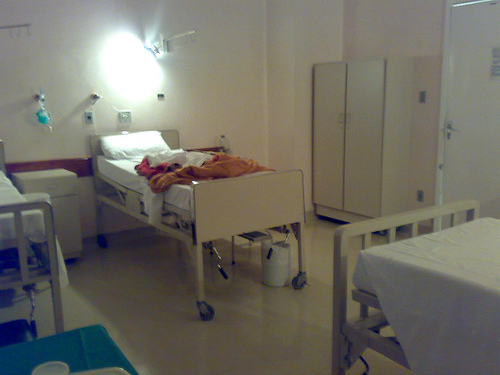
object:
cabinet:
[311, 59, 395, 232]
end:
[189, 174, 311, 209]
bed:
[76, 110, 317, 231]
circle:
[93, 34, 178, 110]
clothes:
[128, 145, 194, 167]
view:
[91, 122, 265, 196]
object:
[259, 234, 293, 292]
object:
[80, 111, 95, 125]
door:
[435, 2, 497, 198]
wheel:
[96, 229, 111, 252]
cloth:
[17, 319, 132, 372]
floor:
[139, 321, 211, 365]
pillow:
[98, 124, 179, 157]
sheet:
[160, 148, 198, 161]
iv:
[29, 96, 61, 129]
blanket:
[153, 154, 280, 187]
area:
[329, 10, 403, 51]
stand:
[82, 91, 114, 110]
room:
[4, 9, 499, 354]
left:
[28, 133, 85, 170]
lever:
[439, 120, 471, 151]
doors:
[345, 58, 380, 210]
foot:
[190, 296, 215, 321]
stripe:
[7, 151, 83, 169]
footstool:
[259, 229, 291, 260]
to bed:
[247, 176, 283, 225]